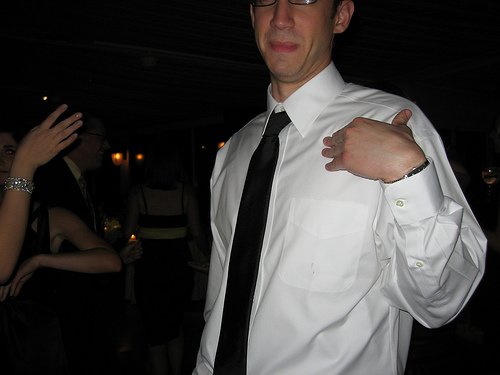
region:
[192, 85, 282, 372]
a long black neck tie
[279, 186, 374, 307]
a white shirt pocket.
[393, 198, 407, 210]
a small white cuff button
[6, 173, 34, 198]
a silver bracelet on a wrist.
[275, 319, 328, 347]
this shirt is white.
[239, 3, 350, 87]
the face of a grimacing man.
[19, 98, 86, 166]
a hand beckoning to the man.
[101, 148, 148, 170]
two orange lights on the wall.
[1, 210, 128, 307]
the elbow and arm of a woman are visible here.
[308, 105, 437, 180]
the man is has his hand on his chest.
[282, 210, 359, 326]
The shirt is white.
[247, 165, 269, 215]
The tie is black.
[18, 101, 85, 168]
A woman's hand is in the air.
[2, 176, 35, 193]
The woman wears a bracelet.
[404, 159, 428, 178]
The man wears a watch.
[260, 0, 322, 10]
The man wears eyeglasses.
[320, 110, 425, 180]
The man's hand is raised.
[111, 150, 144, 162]
Lights are turned on.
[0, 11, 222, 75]
The background is dark.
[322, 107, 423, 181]
The man's hand is on his chest.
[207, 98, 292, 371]
solid black necktie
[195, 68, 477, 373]
white dress shirt man is wearing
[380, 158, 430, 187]
watch on man's wrist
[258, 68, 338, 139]
collar of white dress shirt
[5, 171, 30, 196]
silver bracelet on woman's wrist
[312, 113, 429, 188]
man's hand touching his shirt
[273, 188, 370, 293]
pocket on the white shirt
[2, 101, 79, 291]
hand and arm of woman wearing bracelet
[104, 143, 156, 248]
candles glowing the background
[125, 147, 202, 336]
woman wearing black dress with whit sash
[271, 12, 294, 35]
nose of a person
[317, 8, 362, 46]
ear of a person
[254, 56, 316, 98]
jaw of a person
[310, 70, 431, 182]
hand of a person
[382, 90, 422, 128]
thumb of a person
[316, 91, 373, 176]
finger of a person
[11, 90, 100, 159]
hand of a person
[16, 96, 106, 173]
finger of a person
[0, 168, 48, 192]
wrist of a person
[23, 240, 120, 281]
arm of a person